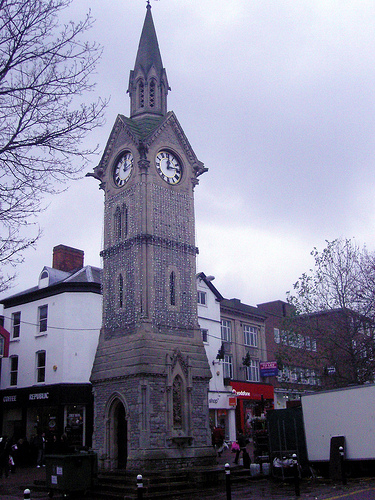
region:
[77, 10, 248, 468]
tall grey clocktower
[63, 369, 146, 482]
arched doorway on tower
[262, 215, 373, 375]
small tree losing its leaves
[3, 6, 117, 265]
bare branches of a tall tree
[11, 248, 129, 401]
large white building with windows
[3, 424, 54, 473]
people standing on a sidewalk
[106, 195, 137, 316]
small arched windows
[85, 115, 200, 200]
a pair of clocks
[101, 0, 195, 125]
pointed top of tower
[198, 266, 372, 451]
group of brown buildings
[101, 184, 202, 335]
lights hanging on the front of the tower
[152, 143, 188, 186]
clock on the top of tower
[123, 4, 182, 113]
steeple at the top of tower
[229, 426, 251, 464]
person holding a pink bag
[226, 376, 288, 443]
red front of store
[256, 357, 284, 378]
sign mounted to building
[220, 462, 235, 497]
protective posts in front of tower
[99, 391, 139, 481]
arched entry door to tower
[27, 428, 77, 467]
crowd of people outside store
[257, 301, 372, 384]
red brick buildings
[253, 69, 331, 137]
sky above the ground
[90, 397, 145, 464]
door on the building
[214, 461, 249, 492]
pole on the ground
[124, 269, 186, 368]
gray structure next to street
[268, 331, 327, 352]
windows on the building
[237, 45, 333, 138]
cloud in the air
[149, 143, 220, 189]
white clock with black numbers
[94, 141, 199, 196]
two clocks on the structure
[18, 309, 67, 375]
two different windows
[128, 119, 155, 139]
roof of the building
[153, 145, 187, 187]
a clock on the tower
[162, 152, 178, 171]
the hands of a clock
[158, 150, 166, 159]
a number on the clock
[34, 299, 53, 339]
a window on the building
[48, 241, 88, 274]
a chimney on the building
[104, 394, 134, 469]
a door on the tower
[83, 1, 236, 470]
a tall clock tower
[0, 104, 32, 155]
the branch of a tree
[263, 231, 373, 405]
a tree by the building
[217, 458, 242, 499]
a metal pole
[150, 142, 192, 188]
Clock face.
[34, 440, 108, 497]
Rolling trash bin.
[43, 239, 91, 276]
Brick chimney on building roof.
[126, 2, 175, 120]
Spire on top of clock tower.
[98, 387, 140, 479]
Entrance to clock tower.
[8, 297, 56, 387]
Four windows on white building.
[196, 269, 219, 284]
Street light on white building.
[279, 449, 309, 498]
Black pole with white tip.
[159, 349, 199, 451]
Decorative window on clock tower.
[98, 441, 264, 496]
Stairs at bottom of clock tower.